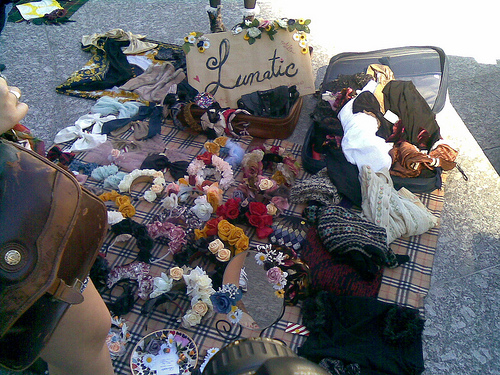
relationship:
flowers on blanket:
[192, 300, 207, 316] [16, 25, 461, 375]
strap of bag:
[49, 271, 90, 316] [2, 138, 108, 375]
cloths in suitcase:
[344, 84, 435, 188] [307, 21, 468, 235]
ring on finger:
[13, 87, 20, 98] [6, 84, 21, 106]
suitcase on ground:
[307, 21, 468, 235] [2, 4, 499, 375]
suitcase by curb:
[307, 21, 468, 235] [440, 94, 499, 198]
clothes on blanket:
[304, 171, 422, 325] [16, 25, 461, 375]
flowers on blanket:
[109, 123, 290, 340] [16, 25, 461, 375]